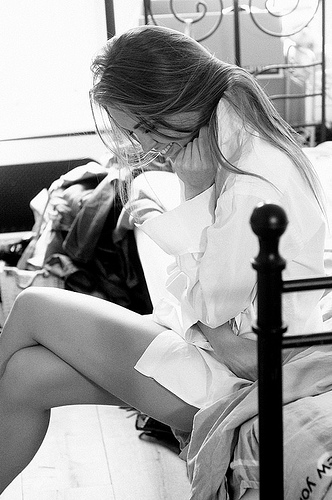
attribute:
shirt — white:
[126, 107, 329, 380]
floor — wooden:
[53, 409, 147, 498]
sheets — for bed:
[181, 397, 330, 496]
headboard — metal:
[84, 0, 328, 132]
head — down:
[77, 17, 293, 198]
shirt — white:
[132, 93, 327, 411]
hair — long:
[85, 25, 325, 200]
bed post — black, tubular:
[247, 205, 283, 499]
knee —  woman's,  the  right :
[4, 342, 50, 405]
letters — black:
[284, 454, 325, 499]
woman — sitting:
[82, 32, 254, 188]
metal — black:
[234, 204, 330, 454]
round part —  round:
[247, 202, 288, 270]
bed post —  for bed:
[248, 199, 286, 498]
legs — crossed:
[0, 285, 201, 495]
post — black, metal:
[249, 200, 289, 497]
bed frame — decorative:
[99, 6, 329, 187]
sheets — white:
[122, 140, 330, 354]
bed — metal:
[230, 209, 330, 492]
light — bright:
[0, 6, 138, 143]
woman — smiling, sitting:
[1, 26, 325, 497]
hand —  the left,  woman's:
[172, 127, 216, 189]